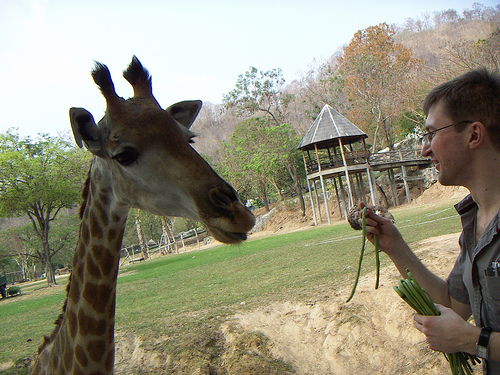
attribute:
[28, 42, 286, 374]
giraffe — spotted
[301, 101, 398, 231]
platform — wooden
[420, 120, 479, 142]
glasses — black framed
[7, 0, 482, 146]
sky — blue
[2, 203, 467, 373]
grass —  green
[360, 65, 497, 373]
man —  smiling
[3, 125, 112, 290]
tree — tall, mature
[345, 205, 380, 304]
celery — green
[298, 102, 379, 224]
gazebo — wooden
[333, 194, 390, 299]
plants — green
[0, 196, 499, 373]
grass — green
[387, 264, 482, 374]
celery — green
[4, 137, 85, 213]
tree —  in background,  tall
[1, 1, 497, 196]
sky — blue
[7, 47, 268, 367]
giraffe — spotted, tan and brown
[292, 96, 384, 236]
platform — wooden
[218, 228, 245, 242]
tongue — sticking out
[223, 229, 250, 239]
tongue —  giraffe's,  out